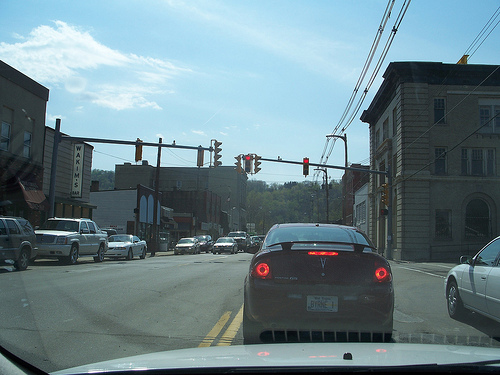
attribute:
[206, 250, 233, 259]
lines — yellow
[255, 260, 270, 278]
tail light — on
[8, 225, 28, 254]
truck — white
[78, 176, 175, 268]
building — brown, white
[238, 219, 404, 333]
car — sitting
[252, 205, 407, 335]
black car — small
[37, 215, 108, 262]
cars — parked, parallel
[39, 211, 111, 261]
truck — white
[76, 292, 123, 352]
asphalt — gray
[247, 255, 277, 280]
light — red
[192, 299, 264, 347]
lines — yellow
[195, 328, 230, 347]
lines — yellow, double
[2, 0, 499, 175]
sky — blue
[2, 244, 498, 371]
pavement — gray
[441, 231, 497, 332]
car — gray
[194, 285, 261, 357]
line — double, yellow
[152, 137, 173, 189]
bars — metal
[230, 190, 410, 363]
car — white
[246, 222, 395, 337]
car — black